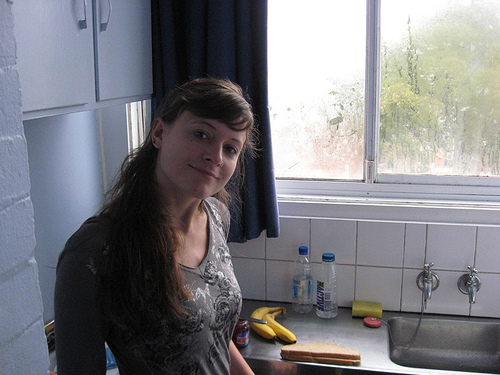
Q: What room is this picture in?
A: It is at the kitchen.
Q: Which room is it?
A: It is a kitchen.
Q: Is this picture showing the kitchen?
A: Yes, it is showing the kitchen.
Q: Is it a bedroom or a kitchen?
A: It is a kitchen.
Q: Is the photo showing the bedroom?
A: No, the picture is showing the kitchen.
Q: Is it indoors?
A: Yes, it is indoors.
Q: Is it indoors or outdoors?
A: It is indoors.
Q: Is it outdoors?
A: No, it is indoors.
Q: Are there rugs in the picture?
A: No, there are no rugs.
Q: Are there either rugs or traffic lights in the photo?
A: No, there are no rugs or traffic lights.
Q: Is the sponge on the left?
A: No, the sponge is on the right of the image.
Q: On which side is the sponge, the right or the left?
A: The sponge is on the right of the image.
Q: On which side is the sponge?
A: The sponge is on the right of the image.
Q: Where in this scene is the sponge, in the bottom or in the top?
A: The sponge is in the bottom of the image.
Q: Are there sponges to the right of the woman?
A: Yes, there is a sponge to the right of the woman.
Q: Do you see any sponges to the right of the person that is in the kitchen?
A: Yes, there is a sponge to the right of the woman.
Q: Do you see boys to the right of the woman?
A: No, there is a sponge to the right of the woman.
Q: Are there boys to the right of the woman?
A: No, there is a sponge to the right of the woman.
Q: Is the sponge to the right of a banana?
A: Yes, the sponge is to the right of a banana.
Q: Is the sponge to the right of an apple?
A: No, the sponge is to the right of a banana.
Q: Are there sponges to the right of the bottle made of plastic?
A: Yes, there is a sponge to the right of the bottle.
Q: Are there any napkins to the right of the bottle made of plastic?
A: No, there is a sponge to the right of the bottle.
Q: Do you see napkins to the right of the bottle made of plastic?
A: No, there is a sponge to the right of the bottle.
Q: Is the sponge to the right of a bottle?
A: Yes, the sponge is to the right of a bottle.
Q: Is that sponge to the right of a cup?
A: No, the sponge is to the right of a bottle.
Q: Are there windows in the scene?
A: Yes, there is a window.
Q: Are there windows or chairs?
A: Yes, there is a window.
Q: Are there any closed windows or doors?
A: Yes, there is a closed window.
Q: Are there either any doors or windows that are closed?
A: Yes, the window is closed.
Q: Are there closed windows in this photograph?
A: Yes, there is a closed window.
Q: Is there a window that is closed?
A: Yes, there is a window that is closed.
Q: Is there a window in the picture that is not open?
A: Yes, there is an closed window.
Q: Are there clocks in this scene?
A: No, there are no clocks.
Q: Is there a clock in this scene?
A: No, there are no clocks.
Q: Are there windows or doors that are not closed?
A: No, there is a window but it is closed.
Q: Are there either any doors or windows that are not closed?
A: No, there is a window but it is closed.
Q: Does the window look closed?
A: Yes, the window is closed.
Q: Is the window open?
A: No, the window is closed.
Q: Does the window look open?
A: No, the window is closed.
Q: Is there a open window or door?
A: No, there is a window but it is closed.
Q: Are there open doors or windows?
A: No, there is a window but it is closed.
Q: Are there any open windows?
A: No, there is a window but it is closed.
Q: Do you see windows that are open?
A: No, there is a window but it is closed.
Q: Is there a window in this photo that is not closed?
A: No, there is a window but it is closed.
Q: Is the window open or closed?
A: The window is closed.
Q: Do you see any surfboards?
A: No, there are no surfboards.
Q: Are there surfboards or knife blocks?
A: No, there are no surfboards or knife blocks.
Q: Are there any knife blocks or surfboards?
A: No, there are no surfboards or knife blocks.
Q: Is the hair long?
A: Yes, the hair is long.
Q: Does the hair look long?
A: Yes, the hair is long.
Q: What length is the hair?
A: The hair is long.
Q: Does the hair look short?
A: No, the hair is long.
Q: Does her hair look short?
A: No, the hair is long.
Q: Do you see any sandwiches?
A: Yes, there is a sandwich.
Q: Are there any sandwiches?
A: Yes, there is a sandwich.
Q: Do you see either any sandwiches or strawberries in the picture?
A: Yes, there is a sandwich.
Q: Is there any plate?
A: No, there are no plates.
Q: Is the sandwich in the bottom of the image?
A: Yes, the sandwich is in the bottom of the image.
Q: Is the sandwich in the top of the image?
A: No, the sandwich is in the bottom of the image.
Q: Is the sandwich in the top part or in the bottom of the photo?
A: The sandwich is in the bottom of the image.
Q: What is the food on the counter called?
A: The food is a sandwich.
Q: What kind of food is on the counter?
A: The food is a sandwich.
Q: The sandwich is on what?
A: The sandwich is on the counter.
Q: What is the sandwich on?
A: The sandwich is on the counter.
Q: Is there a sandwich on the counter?
A: Yes, there is a sandwich on the counter.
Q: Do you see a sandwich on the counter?
A: Yes, there is a sandwich on the counter.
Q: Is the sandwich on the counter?
A: Yes, the sandwich is on the counter.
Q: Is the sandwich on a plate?
A: No, the sandwich is on the counter.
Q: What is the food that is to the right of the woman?
A: The food is a sandwich.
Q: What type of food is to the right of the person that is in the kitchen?
A: The food is a sandwich.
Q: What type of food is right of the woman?
A: The food is a sandwich.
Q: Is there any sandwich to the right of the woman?
A: Yes, there is a sandwich to the right of the woman.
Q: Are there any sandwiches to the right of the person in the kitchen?
A: Yes, there is a sandwich to the right of the woman.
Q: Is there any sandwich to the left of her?
A: No, the sandwich is to the right of the woman.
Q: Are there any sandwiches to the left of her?
A: No, the sandwich is to the right of the woman.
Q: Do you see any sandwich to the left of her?
A: No, the sandwich is to the right of the woman.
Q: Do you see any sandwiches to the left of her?
A: No, the sandwich is to the right of the woman.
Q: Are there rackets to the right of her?
A: No, there is a sandwich to the right of the woman.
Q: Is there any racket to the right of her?
A: No, there is a sandwich to the right of the woman.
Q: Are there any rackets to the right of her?
A: No, there is a sandwich to the right of the woman.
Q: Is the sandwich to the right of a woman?
A: Yes, the sandwich is to the right of a woman.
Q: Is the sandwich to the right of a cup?
A: No, the sandwich is to the right of a woman.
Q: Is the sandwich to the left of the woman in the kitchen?
A: No, the sandwich is to the right of the woman.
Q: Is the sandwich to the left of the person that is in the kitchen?
A: No, the sandwich is to the right of the woman.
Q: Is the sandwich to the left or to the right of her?
A: The sandwich is to the right of the woman.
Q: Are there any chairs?
A: No, there are no chairs.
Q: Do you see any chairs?
A: No, there are no chairs.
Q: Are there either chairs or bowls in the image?
A: No, there are no chairs or bowls.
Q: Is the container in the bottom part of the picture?
A: Yes, the container is in the bottom of the image.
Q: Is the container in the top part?
A: No, the container is in the bottom of the image.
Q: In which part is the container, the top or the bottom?
A: The container is in the bottom of the image.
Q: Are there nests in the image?
A: No, there are no nests.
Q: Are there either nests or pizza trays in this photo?
A: No, there are no nests or pizza trays.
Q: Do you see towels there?
A: No, there are no towels.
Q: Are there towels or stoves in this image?
A: No, there are no towels or stoves.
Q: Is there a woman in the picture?
A: Yes, there is a woman.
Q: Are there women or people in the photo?
A: Yes, there is a woman.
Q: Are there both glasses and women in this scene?
A: No, there is a woman but no glasses.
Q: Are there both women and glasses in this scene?
A: No, there is a woman but no glasses.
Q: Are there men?
A: No, there are no men.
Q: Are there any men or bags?
A: No, there are no men or bags.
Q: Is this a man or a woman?
A: This is a woman.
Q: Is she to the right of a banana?
A: No, the woman is to the left of a banana.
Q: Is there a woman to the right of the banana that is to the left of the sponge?
A: No, the woman is to the left of the banana.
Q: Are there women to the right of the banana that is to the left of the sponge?
A: No, the woman is to the left of the banana.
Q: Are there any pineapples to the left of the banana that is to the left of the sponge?
A: No, there is a woman to the left of the banana.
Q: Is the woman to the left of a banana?
A: Yes, the woman is to the left of a banana.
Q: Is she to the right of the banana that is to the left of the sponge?
A: No, the woman is to the left of the banana.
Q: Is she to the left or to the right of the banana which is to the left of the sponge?
A: The woman is to the left of the banana.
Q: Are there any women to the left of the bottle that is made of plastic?
A: Yes, there is a woman to the left of the bottle.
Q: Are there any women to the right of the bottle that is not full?
A: No, the woman is to the left of the bottle.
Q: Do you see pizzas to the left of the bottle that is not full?
A: No, there is a woman to the left of the bottle.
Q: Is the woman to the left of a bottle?
A: Yes, the woman is to the left of a bottle.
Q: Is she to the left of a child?
A: No, the woman is to the left of a bottle.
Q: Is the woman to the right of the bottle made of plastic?
A: No, the woman is to the left of the bottle.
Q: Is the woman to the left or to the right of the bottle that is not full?
A: The woman is to the left of the bottle.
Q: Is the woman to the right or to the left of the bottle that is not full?
A: The woman is to the left of the bottle.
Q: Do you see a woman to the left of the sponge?
A: Yes, there is a woman to the left of the sponge.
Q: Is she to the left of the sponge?
A: Yes, the woman is to the left of the sponge.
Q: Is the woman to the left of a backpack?
A: No, the woman is to the left of the sponge.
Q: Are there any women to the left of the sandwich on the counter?
A: Yes, there is a woman to the left of the sandwich.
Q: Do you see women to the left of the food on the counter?
A: Yes, there is a woman to the left of the sandwich.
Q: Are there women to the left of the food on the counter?
A: Yes, there is a woman to the left of the sandwich.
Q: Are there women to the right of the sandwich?
A: No, the woman is to the left of the sandwich.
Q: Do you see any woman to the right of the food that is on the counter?
A: No, the woman is to the left of the sandwich.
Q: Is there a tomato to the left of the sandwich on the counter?
A: No, there is a woman to the left of the sandwich.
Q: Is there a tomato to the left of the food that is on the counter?
A: No, there is a woman to the left of the sandwich.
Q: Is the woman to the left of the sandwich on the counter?
A: Yes, the woman is to the left of the sandwich.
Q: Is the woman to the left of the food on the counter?
A: Yes, the woman is to the left of the sandwich.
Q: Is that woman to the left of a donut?
A: No, the woman is to the left of the sandwich.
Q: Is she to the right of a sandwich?
A: No, the woman is to the left of a sandwich.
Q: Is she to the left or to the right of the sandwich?
A: The woman is to the left of the sandwich.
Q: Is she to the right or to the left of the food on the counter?
A: The woman is to the left of the sandwich.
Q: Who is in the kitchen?
A: The woman is in the kitchen.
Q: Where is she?
A: The woman is in the kitchen.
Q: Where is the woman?
A: The woman is in the kitchen.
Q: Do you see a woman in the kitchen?
A: Yes, there is a woman in the kitchen.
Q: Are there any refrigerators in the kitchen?
A: No, there is a woman in the kitchen.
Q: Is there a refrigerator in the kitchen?
A: No, there is a woman in the kitchen.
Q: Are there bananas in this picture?
A: Yes, there is a banana.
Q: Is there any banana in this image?
A: Yes, there is a banana.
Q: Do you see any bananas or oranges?
A: Yes, there is a banana.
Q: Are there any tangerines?
A: No, there are no tangerines.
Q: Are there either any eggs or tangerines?
A: No, there are no tangerines or eggs.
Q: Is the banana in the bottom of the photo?
A: Yes, the banana is in the bottom of the image.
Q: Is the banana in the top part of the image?
A: No, the banana is in the bottom of the image.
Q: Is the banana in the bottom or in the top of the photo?
A: The banana is in the bottom of the image.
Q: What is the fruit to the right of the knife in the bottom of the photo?
A: The fruit is a banana.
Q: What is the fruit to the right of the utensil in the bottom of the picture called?
A: The fruit is a banana.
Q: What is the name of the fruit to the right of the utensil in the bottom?
A: The fruit is a banana.